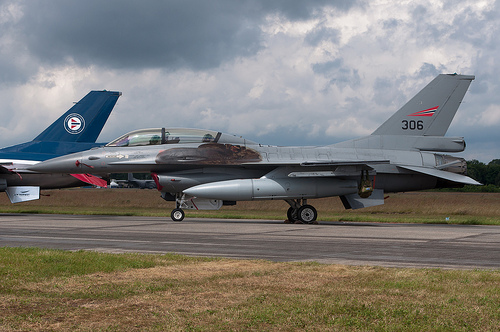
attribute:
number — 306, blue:
[400, 120, 428, 134]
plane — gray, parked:
[28, 71, 485, 223]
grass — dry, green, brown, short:
[4, 251, 499, 331]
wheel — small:
[170, 202, 185, 223]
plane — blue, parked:
[4, 89, 121, 195]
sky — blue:
[1, 3, 499, 168]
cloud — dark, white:
[226, 52, 352, 124]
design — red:
[408, 105, 439, 120]